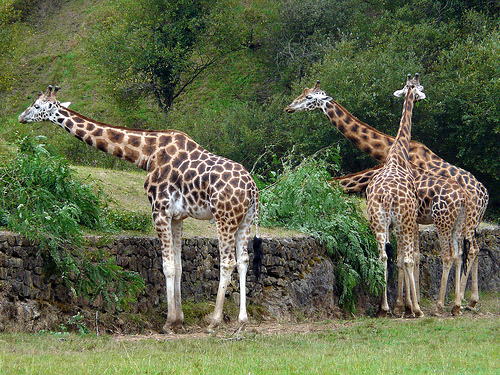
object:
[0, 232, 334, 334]
wall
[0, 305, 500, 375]
grass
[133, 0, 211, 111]
trees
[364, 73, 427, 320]
giraffes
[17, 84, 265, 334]
giraffe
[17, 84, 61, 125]
head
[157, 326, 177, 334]
hooves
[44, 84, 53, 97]
horn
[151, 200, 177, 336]
leg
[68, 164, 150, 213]
grass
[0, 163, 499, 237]
hill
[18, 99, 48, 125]
face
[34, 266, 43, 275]
stones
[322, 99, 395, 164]
neck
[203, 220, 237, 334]
legs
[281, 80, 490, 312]
giraffe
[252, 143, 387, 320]
bush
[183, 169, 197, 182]
spots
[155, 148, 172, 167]
spot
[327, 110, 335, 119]
spot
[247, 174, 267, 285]
tail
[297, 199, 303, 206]
leaves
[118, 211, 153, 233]
bushes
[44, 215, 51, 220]
foliage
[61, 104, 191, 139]
mane